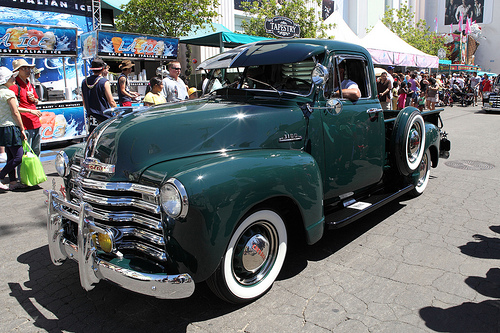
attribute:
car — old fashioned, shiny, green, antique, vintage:
[43, 38, 450, 306]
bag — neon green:
[19, 139, 47, 187]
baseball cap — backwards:
[89, 57, 108, 73]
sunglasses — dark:
[171, 65, 183, 72]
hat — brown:
[11, 59, 37, 73]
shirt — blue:
[82, 76, 114, 120]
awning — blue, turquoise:
[102, 0, 278, 47]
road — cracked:
[0, 100, 500, 332]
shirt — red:
[11, 77, 43, 130]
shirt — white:
[0, 87, 20, 127]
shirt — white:
[326, 76, 360, 97]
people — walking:
[0, 56, 500, 196]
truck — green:
[46, 37, 451, 303]